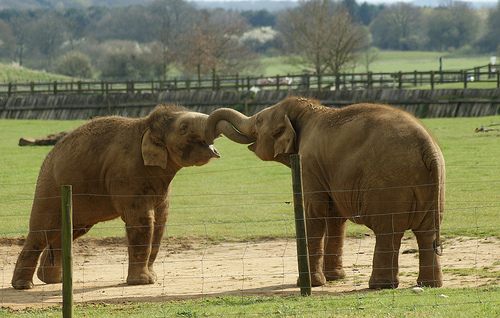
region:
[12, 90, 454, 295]
two elephants are greeting each other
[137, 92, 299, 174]
the ears of the elephants are small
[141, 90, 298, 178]
both elephants' mouths are open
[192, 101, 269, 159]
the elephants' trunks are curled together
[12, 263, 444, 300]
the brown elephants have toe nails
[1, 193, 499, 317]
the elephants are in the pen's brown patch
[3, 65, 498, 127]
sturdy fencing is behind the elephants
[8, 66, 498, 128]
the enclosure has wooden fencing and logs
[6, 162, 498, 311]
post and wire fencing is in front of the elephants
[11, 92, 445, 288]
Two elephants with intertwined trunks.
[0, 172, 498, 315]
A wire fence.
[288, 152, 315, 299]
A wooden fence post.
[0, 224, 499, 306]
A patch of dirt on the ground.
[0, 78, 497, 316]
A large elephant enclosure.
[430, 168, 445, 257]
An elephant's tail.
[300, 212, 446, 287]
An elephant's legs.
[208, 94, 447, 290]
An elephant facing left.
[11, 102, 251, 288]
An elephant facing right.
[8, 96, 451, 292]
Two elephants facing one another.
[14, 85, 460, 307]
two elephants face-to-face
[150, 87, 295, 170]
two trunks together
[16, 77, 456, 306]
two elephants are playing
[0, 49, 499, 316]
elephants are enclosed in a pen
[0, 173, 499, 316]
metal wires of a fence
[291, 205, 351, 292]
front legs of elephant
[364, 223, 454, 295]
back legs of elephant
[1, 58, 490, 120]
fence of pen is made of wood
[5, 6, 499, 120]
trees in the background of a pen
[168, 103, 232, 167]
mouth of elephant is open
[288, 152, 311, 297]
green wooden fence post in front of elephant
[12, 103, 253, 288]
elephant playing with another elephant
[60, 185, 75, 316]
fence post to the left of fence post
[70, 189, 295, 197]
barbed wire connected to fence post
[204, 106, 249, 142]
trunk touching trunk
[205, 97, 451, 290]
large brown elephant is standing on sand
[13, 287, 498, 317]
grass in front of elephant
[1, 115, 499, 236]
grass behind elephant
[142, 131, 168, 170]
brown elephant ear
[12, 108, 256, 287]
elephant is smiling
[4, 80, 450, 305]
two elephants in a joyous mood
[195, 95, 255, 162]
trunk to trunk, trunk to mouth, w/ feeling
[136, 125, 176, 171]
a reasonably tiny elephant ear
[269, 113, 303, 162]
another small ear, this one more foldy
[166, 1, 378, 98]
several trees in autumn colours in the middle distance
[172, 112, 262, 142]
elephant eye to elephant eye, seeing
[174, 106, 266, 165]
the happy expressions on the faces of two delighted elephants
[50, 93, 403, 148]
elephant frizz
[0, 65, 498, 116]
long grey fence closed slatted fence, leaning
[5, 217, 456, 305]
eight sturdy feet @ the end of eight sturdy legs